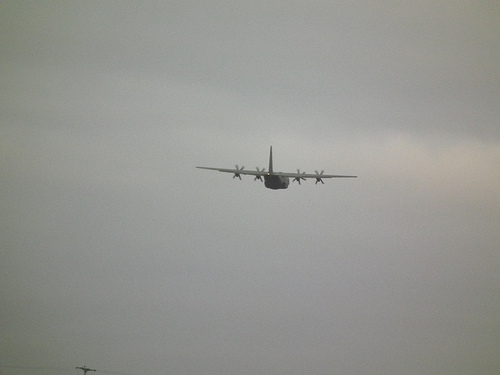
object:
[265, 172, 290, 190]
body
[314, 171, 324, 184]
engine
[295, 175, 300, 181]
engine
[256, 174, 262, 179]
engine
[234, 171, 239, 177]
engine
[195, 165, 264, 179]
plane wing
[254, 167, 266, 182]
propeller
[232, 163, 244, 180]
propeller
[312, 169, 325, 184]
propeller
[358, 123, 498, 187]
cloud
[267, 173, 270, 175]
light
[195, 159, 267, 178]
wing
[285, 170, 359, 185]
right wing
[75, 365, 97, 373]
electrical pole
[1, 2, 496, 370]
sky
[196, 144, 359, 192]
aircraft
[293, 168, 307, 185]
propeller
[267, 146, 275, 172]
raised tail